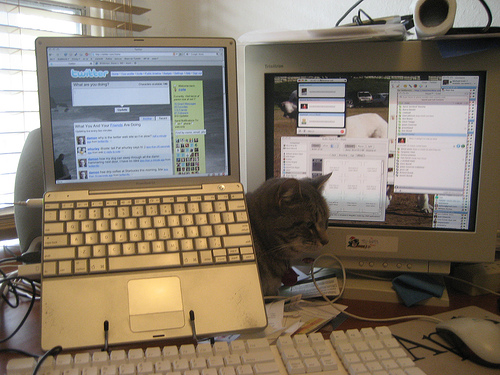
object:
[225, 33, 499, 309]
computer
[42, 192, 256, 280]
keyboard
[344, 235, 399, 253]
sign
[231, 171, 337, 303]
grey cat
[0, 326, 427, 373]
white keyboard